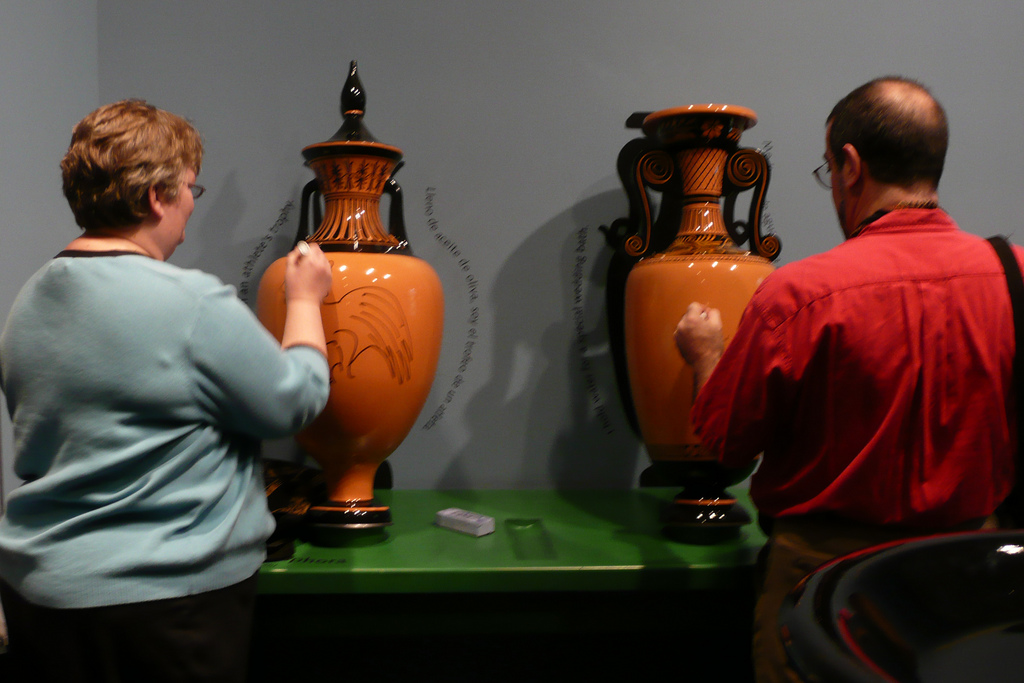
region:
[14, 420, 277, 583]
wrinkles on the shirt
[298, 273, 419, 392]
black design on the vase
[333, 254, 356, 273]
small light glare on the vase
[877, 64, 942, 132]
bald spot on the back of the head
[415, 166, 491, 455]
writing on the wall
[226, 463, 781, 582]
tabletop is green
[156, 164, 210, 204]
glasses are on the face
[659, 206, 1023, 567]
long sleeved red shirt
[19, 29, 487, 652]
woman drawing a design on the vase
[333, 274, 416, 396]
design on the vase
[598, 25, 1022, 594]
man drawing a design on the vase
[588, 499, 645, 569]
green table the vases are on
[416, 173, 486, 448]
words on the grey wall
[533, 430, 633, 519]
shadow of the vase on the wall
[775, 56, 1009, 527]
man is wearing a red shirt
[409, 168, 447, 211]
Black letters on the wall.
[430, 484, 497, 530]
Small purple box on the table.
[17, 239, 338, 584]
Blue sweater on the woman's body.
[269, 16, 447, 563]
Large tan vase on the table.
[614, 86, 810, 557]
Smaller blonde vase on the table.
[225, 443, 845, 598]
Green table with statues on it.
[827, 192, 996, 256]
Black string around the man's neck.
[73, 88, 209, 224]
Woman has short hair.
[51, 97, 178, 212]
Woman has brown hair.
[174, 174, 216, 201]
Glasses on woman's face.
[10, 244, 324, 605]
Woman wearing blue shirt.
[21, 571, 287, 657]
Woman wearing black pants.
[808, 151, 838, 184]
Glasses on man's face.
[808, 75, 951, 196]
Man has short hair.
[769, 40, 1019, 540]
man wearing a red shirt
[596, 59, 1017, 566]
man drawing on the vase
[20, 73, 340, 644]
woman drawing on the vase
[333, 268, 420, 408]
decorative design on the vase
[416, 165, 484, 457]
word on the wall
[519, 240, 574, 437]
shadow of the vase on the wall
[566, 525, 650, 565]
green table the vases are on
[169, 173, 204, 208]
glasses on the woman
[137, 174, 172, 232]
ear of the woman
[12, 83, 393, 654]
overweight woman with cyan sweater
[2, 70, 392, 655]
overweight woman with cyan sweater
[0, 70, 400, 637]
overweight woman with cyan sweater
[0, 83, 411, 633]
overweight woman with cyan sweater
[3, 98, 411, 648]
overweight woman with cyan sweater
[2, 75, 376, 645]
overweight woman with cyan sweater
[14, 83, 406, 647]
overweight woman with cyan sweater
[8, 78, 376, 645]
overweight woman with cyan sweater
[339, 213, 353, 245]
black stripe on the orange vase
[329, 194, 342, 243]
black stripe on the orange vase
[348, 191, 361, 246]
black stripe on the orange vase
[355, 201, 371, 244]
black stripe on the orange vase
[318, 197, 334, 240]
black stripe on the orange vase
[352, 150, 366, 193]
black stripe on the orange vase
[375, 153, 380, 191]
black stripe on the orange vase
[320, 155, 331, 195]
black stripe on the orange vase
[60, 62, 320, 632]
a woman standing inside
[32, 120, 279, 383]
a woman with short hair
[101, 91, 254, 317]
a woman wearin gblonde hair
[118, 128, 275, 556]
a woman weraing a blue shirt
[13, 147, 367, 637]
a woman wearing a long sleeve shirt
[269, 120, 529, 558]
a pot on the table